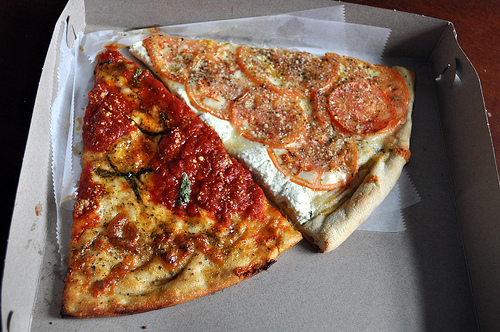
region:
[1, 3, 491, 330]
two slices of pizza in a box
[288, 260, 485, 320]
a cardboard box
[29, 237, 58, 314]
a splattering of grease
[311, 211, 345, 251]
the crust of a pizza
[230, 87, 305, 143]
a thinly sliced tomato on a pizza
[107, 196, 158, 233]
melted cheese on a pizza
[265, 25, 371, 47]
a piece of parchment paper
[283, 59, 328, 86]
seasoning on top of a tomato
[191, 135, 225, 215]
tomato sauce on a pizza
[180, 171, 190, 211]
a piece of an herb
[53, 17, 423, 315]
Two slices of pizza.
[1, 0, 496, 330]
The pizza is in a box.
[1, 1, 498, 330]
The box is made of cardboard.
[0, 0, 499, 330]
The box is gray.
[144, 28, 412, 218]
The pepperoni is round.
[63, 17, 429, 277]
Paper is under the pizza.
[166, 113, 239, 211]
The pizza sauce is red.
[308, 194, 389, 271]
The pizza crust is white.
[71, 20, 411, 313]
Two different types of pizza.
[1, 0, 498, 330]
Two slices of pizza in a box.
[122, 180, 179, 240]
a slice of pizza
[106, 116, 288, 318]
a slice of pizza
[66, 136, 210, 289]
a slice of pizza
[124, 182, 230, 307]
a slice of pizza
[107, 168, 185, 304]
a slice of pizza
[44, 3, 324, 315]
a slice of pizza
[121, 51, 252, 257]
a slice of pizza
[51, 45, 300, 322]
a slice of pepperoni pizza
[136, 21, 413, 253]
a slice of pepperoni pizza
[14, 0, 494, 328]
a cardboard food box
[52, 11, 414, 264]
two pieces of wax paper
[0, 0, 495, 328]
food in a box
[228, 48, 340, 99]
a slice of pepperoni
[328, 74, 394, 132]
a slice of pepperoni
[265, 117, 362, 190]
a slice of pepperoni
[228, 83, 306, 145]
a slice of pepperoni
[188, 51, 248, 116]
a slice of pepperoni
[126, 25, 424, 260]
a slice of pizza in the box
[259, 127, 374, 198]
a red tomato slice on the pizza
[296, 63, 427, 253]
the crust of a pizza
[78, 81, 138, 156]
red tomato sauce on the pizza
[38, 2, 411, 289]
white paper under the pizza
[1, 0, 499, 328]
a gray cardboard box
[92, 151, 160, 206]
green plants on the pizza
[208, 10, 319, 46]
grease on the paper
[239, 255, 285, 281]
a black spot on the pizza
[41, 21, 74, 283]
a serrated edge on the paper